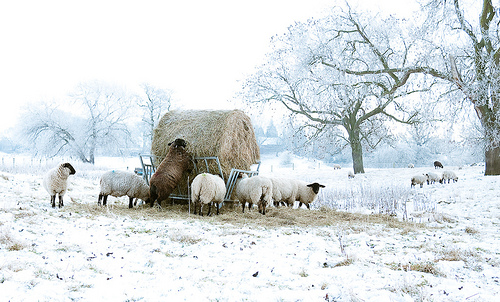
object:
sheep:
[432, 160, 444, 169]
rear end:
[189, 172, 202, 204]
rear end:
[253, 180, 261, 205]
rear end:
[148, 174, 165, 206]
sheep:
[441, 171, 458, 186]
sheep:
[144, 133, 191, 212]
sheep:
[235, 173, 274, 216]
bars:
[122, 149, 260, 211]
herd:
[408, 175, 428, 188]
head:
[59, 162, 77, 177]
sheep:
[293, 182, 325, 210]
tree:
[226, 10, 454, 175]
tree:
[127, 81, 179, 155]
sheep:
[423, 171, 444, 183]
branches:
[254, 20, 434, 130]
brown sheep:
[147, 138, 196, 207]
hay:
[151, 108, 260, 200]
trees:
[305, 0, 499, 175]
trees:
[20, 83, 140, 165]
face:
[62, 163, 75, 173]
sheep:
[97, 171, 151, 208]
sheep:
[187, 173, 227, 216]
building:
[260, 137, 284, 153]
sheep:
[270, 176, 298, 209]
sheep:
[410, 174, 428, 188]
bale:
[151, 109, 261, 197]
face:
[312, 183, 320, 192]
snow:
[244, 4, 409, 120]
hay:
[64, 196, 424, 230]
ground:
[0, 156, 499, 301]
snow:
[0, 155, 500, 302]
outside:
[0, 0, 499, 302]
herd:
[45, 163, 75, 208]